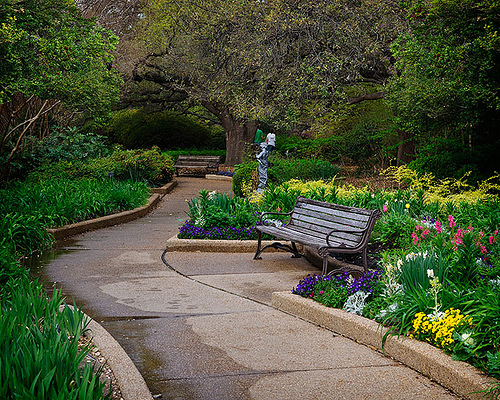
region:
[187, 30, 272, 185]
This is a tree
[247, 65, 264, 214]
This is a tree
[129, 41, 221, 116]
This is a tree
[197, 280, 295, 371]
This is a tree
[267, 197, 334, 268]
This is a tree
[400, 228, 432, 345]
This is a tree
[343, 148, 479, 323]
This is a tree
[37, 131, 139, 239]
This is a tree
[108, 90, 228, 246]
This is a tree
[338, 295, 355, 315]
part of a flower bed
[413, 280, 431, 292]
part of flower bed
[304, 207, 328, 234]
part of a bench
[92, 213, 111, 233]
edge of a pavement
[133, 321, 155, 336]
edge of a path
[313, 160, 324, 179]
part of a bush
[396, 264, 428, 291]
part of a garden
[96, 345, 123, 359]
edge of a path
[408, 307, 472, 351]
A group of yellow flowers.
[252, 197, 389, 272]
A small grey bench.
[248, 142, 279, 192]
A small grey statue.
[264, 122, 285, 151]
A woman in a white shirt.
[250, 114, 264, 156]
A man in a green shirt.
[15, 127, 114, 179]
A group of bushes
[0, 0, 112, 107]
A set of green trees.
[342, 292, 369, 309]
A set of white flowers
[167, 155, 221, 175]
A far-away brown bench.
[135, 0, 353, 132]
A big yellow tree.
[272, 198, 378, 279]
This bench is old and grey.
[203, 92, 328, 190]
Theese people look happy.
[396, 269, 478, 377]
Yellow flowers are beautiful.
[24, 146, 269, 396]
This sidewalk is wet.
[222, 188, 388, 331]
purple is my favorite color.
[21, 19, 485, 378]
Everything in this garden is alive.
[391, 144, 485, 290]
Pink flowers are beautiful.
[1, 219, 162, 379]
This grass is verry healthy.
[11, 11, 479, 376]
This is a garden full of flowers and trees.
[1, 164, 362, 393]
The congreet is very wet.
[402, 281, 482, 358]
the flowers are yelllow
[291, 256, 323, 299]
the flowers are purple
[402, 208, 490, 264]
the flowers are pink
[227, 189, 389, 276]
bench in middle of flowers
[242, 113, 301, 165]
people walking through park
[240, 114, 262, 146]
person's shirt is green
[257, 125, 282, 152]
person's shirt is white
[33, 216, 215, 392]
the ground is wet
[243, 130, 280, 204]
statue in middle of flowers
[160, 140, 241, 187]
bench in the distance